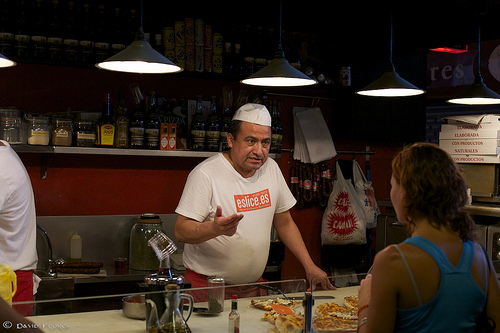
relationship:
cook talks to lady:
[171, 100, 339, 303] [362, 138, 500, 332]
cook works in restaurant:
[168, 106, 346, 287] [49, 20, 486, 305]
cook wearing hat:
[171, 100, 339, 303] [230, 102, 270, 123]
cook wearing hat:
[171, 100, 339, 303] [227, 99, 272, 127]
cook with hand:
[171, 100, 339, 303] [210, 202, 244, 239]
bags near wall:
[322, 156, 380, 246] [4, 114, 438, 301]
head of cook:
[225, 104, 272, 171] [171, 100, 339, 303]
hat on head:
[234, 102, 271, 124] [224, 100, 275, 169]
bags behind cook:
[317, 158, 382, 246] [171, 100, 339, 303]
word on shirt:
[228, 184, 272, 218] [173, 154, 293, 273]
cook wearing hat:
[171, 100, 339, 303] [227, 95, 275, 129]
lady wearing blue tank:
[350, 136, 498, 330] [393, 235, 491, 333]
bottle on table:
[142, 282, 194, 332] [25, 229, 408, 333]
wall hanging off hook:
[180, 66, 282, 127] [315, 150, 359, 171]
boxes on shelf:
[433, 127, 499, 146] [421, 109, 498, 243]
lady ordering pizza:
[350, 136, 498, 330] [250, 290, 357, 331]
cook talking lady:
[171, 100, 339, 303] [362, 138, 500, 332]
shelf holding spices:
[9, 140, 277, 181] [0, 84, 286, 156]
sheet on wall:
[297, 101, 339, 168] [16, 102, 433, 304]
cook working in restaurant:
[171, 100, 339, 303] [2, 2, 497, 329]